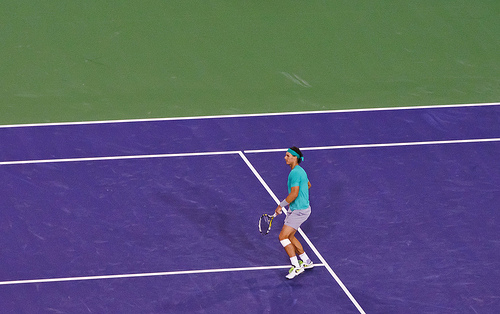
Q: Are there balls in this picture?
A: No, there are no balls.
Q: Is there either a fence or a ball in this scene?
A: No, there are no balls or fences.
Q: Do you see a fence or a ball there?
A: No, there are no balls or fences.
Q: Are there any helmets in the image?
A: No, there are no helmets.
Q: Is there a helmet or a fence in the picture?
A: No, there are no helmets or fences.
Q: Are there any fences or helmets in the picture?
A: No, there are no helmets or fences.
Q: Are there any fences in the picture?
A: No, there are no fences.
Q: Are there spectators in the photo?
A: No, there are no spectators.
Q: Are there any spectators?
A: No, there are no spectators.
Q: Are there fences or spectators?
A: No, there are no spectators or fences.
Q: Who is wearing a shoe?
A: The man is wearing a shoe.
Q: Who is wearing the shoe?
A: The man is wearing a shoe.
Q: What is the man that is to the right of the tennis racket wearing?
A: The man is wearing a shoe.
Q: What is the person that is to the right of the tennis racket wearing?
A: The man is wearing a shoe.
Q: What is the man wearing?
A: The man is wearing a shoe.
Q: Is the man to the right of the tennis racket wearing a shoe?
A: Yes, the man is wearing a shoe.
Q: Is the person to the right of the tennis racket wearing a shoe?
A: Yes, the man is wearing a shoe.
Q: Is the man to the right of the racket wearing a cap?
A: No, the man is wearing a shoe.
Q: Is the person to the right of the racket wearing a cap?
A: No, the man is wearing a shoe.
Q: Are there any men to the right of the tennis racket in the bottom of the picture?
A: Yes, there is a man to the right of the racket.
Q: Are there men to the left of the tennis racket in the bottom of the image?
A: No, the man is to the right of the racket.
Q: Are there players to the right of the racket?
A: No, there is a man to the right of the racket.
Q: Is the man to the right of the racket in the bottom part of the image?
A: Yes, the man is to the right of the racket.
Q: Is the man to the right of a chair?
A: No, the man is to the right of the racket.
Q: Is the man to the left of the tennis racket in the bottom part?
A: No, the man is to the right of the racket.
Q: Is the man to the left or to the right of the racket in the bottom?
A: The man is to the right of the racket.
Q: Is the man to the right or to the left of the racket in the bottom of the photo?
A: The man is to the right of the racket.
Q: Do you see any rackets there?
A: Yes, there is a racket.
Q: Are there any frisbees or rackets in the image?
A: Yes, there is a racket.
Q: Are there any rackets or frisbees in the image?
A: Yes, there is a racket.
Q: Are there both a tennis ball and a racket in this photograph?
A: No, there is a racket but no tennis balls.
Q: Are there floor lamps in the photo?
A: No, there are no floor lamps.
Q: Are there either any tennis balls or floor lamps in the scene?
A: No, there are no floor lamps or tennis balls.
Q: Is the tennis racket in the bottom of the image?
A: Yes, the tennis racket is in the bottom of the image.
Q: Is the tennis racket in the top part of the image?
A: No, the tennis racket is in the bottom of the image.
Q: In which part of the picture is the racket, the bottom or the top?
A: The racket is in the bottom of the image.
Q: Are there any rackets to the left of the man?
A: Yes, there is a racket to the left of the man.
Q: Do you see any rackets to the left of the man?
A: Yes, there is a racket to the left of the man.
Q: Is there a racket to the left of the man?
A: Yes, there is a racket to the left of the man.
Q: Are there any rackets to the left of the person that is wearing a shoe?
A: Yes, there is a racket to the left of the man.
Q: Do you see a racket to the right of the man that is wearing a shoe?
A: No, the racket is to the left of the man.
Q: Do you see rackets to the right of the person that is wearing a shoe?
A: No, the racket is to the left of the man.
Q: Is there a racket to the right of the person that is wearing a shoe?
A: No, the racket is to the left of the man.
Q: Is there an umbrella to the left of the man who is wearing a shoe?
A: No, there is a racket to the left of the man.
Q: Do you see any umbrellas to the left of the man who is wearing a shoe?
A: No, there is a racket to the left of the man.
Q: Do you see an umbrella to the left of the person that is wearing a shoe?
A: No, there is a racket to the left of the man.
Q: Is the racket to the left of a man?
A: Yes, the racket is to the left of a man.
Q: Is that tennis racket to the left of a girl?
A: No, the tennis racket is to the left of a man.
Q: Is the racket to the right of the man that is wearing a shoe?
A: No, the racket is to the left of the man.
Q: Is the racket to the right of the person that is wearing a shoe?
A: No, the racket is to the left of the man.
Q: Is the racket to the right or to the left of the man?
A: The racket is to the left of the man.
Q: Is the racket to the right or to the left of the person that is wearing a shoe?
A: The racket is to the left of the man.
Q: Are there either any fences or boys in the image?
A: No, there are no fences or boys.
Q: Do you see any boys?
A: No, there are no boys.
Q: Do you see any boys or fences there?
A: No, there are no boys or fences.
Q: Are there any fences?
A: No, there are no fences.